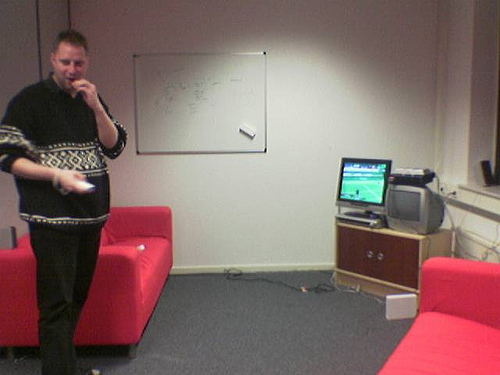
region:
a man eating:
[7, 41, 116, 371]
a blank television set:
[381, 183, 460, 242]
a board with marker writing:
[132, 43, 282, 161]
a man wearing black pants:
[9, 10, 141, 360]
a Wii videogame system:
[372, 280, 423, 321]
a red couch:
[104, 203, 186, 335]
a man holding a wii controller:
[21, 33, 119, 365]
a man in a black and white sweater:
[12, 50, 138, 365]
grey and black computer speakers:
[468, 152, 498, 197]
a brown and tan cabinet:
[317, 231, 449, 286]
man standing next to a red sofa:
[0, 31, 128, 371]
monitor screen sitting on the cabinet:
[336, 156, 391, 207]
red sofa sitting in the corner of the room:
[1, 206, 171, 356]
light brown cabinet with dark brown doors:
[330, 217, 451, 309]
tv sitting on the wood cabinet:
[383, 183, 444, 235]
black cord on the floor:
[222, 266, 332, 293]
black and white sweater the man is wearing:
[2, 70, 130, 234]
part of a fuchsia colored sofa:
[376, 255, 496, 371]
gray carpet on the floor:
[0, 268, 413, 371]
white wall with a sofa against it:
[0, 0, 435, 266]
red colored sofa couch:
[0, 198, 179, 352]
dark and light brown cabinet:
[331, 223, 450, 296]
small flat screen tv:
[337, 150, 388, 210]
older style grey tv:
[383, 184, 448, 234]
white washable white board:
[131, 50, 268, 156]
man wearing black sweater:
[4, 77, 126, 227]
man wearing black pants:
[16, 213, 110, 374]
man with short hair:
[51, 23, 93, 90]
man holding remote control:
[52, 164, 97, 197]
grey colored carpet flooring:
[181, 295, 271, 357]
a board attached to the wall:
[89, 18, 290, 175]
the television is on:
[325, 128, 392, 230]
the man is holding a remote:
[12, 152, 142, 247]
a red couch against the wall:
[10, 166, 190, 336]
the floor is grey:
[193, 287, 353, 362]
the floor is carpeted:
[175, 281, 327, 359]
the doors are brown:
[319, 210, 423, 296]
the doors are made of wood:
[310, 214, 417, 301]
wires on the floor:
[214, 251, 360, 317]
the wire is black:
[205, 252, 342, 304]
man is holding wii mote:
[1, 31, 127, 374]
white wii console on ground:
[385, 293, 417, 320]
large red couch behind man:
[2, 204, 173, 351]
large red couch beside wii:
[378, 257, 498, 374]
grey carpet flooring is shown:
[1, 272, 418, 373]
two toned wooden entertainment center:
[331, 216, 458, 304]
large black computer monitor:
[336, 158, 396, 221]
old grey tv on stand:
[385, 182, 445, 237]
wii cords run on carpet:
[325, 269, 387, 314]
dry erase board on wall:
[136, 51, 267, 155]